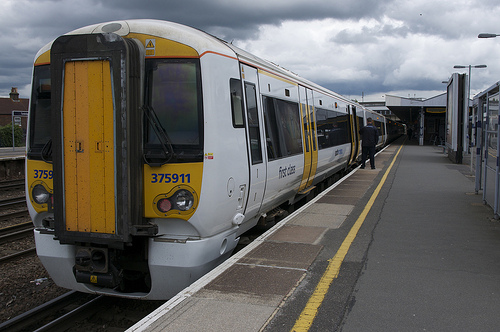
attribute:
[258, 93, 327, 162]
window — rectangular 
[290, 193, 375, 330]
yellow line — thin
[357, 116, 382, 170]
man — head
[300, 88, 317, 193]
double doors — yellow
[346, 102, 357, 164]
double doors — yellow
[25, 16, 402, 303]
train — white, yellow